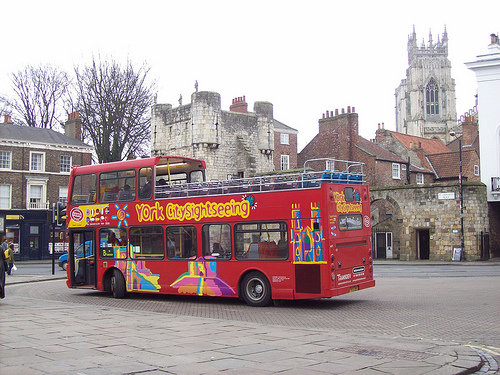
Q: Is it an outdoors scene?
A: Yes, it is outdoors.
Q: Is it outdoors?
A: Yes, it is outdoors.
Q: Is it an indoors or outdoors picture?
A: It is outdoors.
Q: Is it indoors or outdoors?
A: It is outdoors.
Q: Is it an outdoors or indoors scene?
A: It is outdoors.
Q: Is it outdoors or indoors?
A: It is outdoors.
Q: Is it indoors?
A: No, it is outdoors.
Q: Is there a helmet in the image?
A: No, there are no helmets.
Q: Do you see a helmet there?
A: No, there are no helmets.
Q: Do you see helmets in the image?
A: No, there are no helmets.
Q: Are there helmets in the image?
A: No, there are no helmets.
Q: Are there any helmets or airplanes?
A: No, there are no helmets or airplanes.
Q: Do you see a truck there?
A: No, there are no trucks.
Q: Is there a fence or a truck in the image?
A: No, there are no trucks or fences.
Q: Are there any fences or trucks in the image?
A: No, there are no trucks or fences.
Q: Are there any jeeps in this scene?
A: No, there are no jeeps.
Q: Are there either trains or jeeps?
A: No, there are no jeeps or trains.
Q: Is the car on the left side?
A: Yes, the car is on the left of the image.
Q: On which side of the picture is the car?
A: The car is on the left of the image.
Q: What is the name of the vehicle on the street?
A: The vehicle is a car.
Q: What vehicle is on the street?
A: The vehicle is a car.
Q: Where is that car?
A: The car is on the street.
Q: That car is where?
A: The car is on the street.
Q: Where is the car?
A: The car is on the street.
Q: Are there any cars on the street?
A: Yes, there is a car on the street.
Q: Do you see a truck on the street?
A: No, there is a car on the street.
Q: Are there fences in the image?
A: No, there are no fences.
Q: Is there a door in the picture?
A: Yes, there is a door.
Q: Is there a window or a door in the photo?
A: Yes, there is a door.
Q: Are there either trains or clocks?
A: No, there are no trains or clocks.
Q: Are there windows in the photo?
A: Yes, there are windows.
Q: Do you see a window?
A: Yes, there are windows.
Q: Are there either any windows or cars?
A: Yes, there are windows.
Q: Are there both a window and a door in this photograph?
A: Yes, there are both a window and a door.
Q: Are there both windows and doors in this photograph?
A: Yes, there are both windows and a door.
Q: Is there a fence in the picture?
A: No, there are no fences.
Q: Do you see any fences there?
A: No, there are no fences.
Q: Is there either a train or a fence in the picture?
A: No, there are no fences or trains.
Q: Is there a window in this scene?
A: Yes, there are windows.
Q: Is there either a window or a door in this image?
A: Yes, there are windows.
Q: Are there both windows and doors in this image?
A: Yes, there are both windows and a door.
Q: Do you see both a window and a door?
A: Yes, there are both a window and a door.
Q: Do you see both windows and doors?
A: Yes, there are both windows and a door.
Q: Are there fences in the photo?
A: No, there are no fences.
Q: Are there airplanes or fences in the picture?
A: No, there are no fences or airplanes.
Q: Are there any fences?
A: No, there are no fences.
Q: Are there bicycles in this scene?
A: No, there are no bicycles.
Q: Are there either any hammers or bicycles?
A: No, there are no bicycles or hammers.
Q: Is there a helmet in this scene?
A: No, there are no helmets.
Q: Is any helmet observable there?
A: No, there are no helmets.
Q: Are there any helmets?
A: No, there are no helmets.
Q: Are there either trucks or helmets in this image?
A: No, there are no helmets or trucks.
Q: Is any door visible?
A: Yes, there is a door.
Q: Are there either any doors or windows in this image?
A: Yes, there is a door.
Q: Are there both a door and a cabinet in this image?
A: No, there is a door but no cabinets.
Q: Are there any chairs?
A: No, there are no chairs.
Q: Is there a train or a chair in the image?
A: No, there are no chairs or trains.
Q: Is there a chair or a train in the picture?
A: No, there are no chairs or trains.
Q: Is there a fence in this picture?
A: No, there are no fences.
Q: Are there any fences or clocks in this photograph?
A: No, there are no fences or clocks.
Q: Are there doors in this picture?
A: Yes, there is a door.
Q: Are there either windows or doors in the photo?
A: Yes, there is a door.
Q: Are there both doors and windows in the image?
A: Yes, there are both a door and a window.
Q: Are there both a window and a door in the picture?
A: Yes, there are both a door and a window.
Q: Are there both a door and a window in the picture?
A: Yes, there are both a door and a window.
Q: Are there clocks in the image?
A: No, there are no clocks.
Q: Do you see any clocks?
A: No, there are no clocks.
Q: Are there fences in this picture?
A: No, there are no fences.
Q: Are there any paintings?
A: No, there are no paintings.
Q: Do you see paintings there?
A: No, there are no paintings.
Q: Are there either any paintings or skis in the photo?
A: No, there are no paintings or skis.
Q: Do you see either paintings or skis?
A: No, there are no paintings or skis.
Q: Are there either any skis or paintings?
A: No, there are no paintings or skis.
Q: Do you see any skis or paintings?
A: No, there are no paintings or skis.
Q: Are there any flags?
A: No, there are no flags.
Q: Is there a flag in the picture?
A: No, there are no flags.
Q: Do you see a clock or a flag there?
A: No, there are no flags or clocks.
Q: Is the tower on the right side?
A: Yes, the tower is on the right of the image.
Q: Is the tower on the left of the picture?
A: No, the tower is on the right of the image.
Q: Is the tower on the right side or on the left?
A: The tower is on the right of the image.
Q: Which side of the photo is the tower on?
A: The tower is on the right of the image.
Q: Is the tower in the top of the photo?
A: Yes, the tower is in the top of the image.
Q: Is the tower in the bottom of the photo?
A: No, the tower is in the top of the image.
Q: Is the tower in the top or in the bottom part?
A: The tower is in the top of the image.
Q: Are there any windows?
A: Yes, there are windows.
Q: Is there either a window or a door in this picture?
A: Yes, there are windows.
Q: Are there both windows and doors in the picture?
A: Yes, there are both windows and a door.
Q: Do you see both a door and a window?
A: Yes, there are both a window and a door.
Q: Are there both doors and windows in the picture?
A: Yes, there are both windows and a door.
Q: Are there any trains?
A: No, there are no trains.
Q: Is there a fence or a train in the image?
A: No, there are no trains or fences.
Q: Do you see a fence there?
A: No, there are no fences.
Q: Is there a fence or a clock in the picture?
A: No, there are no fences or clocks.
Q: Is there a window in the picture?
A: Yes, there are windows.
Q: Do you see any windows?
A: Yes, there are windows.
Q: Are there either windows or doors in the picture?
A: Yes, there are windows.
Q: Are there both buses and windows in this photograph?
A: Yes, there are both windows and a bus.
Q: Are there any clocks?
A: No, there are no clocks.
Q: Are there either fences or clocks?
A: No, there are no clocks or fences.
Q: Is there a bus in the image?
A: Yes, there is a bus.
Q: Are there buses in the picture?
A: Yes, there is a bus.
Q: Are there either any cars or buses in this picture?
A: Yes, there is a bus.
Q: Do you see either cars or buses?
A: Yes, there is a bus.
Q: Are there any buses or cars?
A: Yes, there is a bus.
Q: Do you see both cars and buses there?
A: Yes, there are both a bus and a car.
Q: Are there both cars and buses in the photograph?
A: Yes, there are both a bus and a car.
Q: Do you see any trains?
A: No, there are no trains.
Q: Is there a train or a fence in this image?
A: No, there are no trains or fences.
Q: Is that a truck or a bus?
A: That is a bus.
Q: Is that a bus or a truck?
A: That is a bus.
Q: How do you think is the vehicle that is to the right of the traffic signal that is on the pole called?
A: The vehicle is a bus.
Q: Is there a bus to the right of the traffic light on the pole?
A: Yes, there is a bus to the right of the signal light.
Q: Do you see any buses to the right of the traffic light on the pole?
A: Yes, there is a bus to the right of the signal light.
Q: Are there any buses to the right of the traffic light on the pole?
A: Yes, there is a bus to the right of the signal light.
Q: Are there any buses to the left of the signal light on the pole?
A: No, the bus is to the right of the traffic light.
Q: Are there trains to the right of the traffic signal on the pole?
A: No, there is a bus to the right of the signal light.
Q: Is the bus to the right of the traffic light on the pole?
A: Yes, the bus is to the right of the traffic light.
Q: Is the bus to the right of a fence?
A: No, the bus is to the right of the traffic light.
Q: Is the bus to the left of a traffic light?
A: No, the bus is to the right of a traffic light.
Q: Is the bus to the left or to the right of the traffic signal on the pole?
A: The bus is to the right of the traffic light.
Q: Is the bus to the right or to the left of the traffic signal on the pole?
A: The bus is to the right of the traffic light.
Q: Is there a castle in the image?
A: Yes, there is a castle.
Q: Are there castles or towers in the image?
A: Yes, there is a castle.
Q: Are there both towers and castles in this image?
A: Yes, there are both a castle and towers.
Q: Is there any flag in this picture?
A: No, there are no flags.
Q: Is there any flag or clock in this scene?
A: No, there are no flags or clocks.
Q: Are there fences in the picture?
A: No, there are no fences.